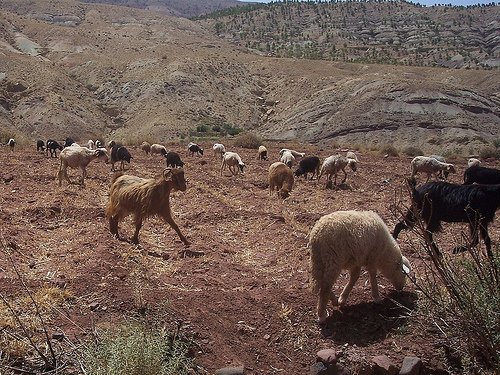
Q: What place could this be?
A: It is a field.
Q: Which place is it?
A: It is a field.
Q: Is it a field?
A: Yes, it is a field.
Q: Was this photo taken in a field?
A: Yes, it was taken in a field.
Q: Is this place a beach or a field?
A: It is a field.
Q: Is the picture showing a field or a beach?
A: It is showing a field.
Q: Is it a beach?
A: No, it is a field.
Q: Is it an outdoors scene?
A: Yes, it is outdoors.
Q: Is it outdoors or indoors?
A: It is outdoors.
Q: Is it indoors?
A: No, it is outdoors.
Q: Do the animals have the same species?
A: No, there are both sheep and goats.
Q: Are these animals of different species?
A: Yes, they are sheep and goats.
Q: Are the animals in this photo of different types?
A: Yes, they are sheep and goats.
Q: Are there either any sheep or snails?
A: Yes, there is a sheep.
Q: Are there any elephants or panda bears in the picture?
A: No, there are no panda bears or elephants.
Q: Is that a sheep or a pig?
A: That is a sheep.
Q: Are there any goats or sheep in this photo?
A: Yes, there is a sheep.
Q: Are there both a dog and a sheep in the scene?
A: No, there is a sheep but no dogs.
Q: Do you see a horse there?
A: No, there are no horses.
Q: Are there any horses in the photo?
A: No, there are no horses.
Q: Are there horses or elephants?
A: No, there are no horses or elephants.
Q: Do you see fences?
A: No, there are no fences.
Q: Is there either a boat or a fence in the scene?
A: No, there are no fences or boats.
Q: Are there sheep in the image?
A: Yes, there is a sheep.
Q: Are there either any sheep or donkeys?
A: Yes, there is a sheep.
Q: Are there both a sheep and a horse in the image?
A: No, there is a sheep but no horses.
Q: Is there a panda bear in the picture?
A: No, there are no panda bears.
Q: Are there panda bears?
A: No, there are no panda bears.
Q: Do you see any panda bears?
A: No, there are no panda bears.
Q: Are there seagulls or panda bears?
A: No, there are no panda bears or seagulls.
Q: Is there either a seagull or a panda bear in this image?
A: No, there are no panda bears or seagulls.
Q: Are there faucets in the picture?
A: No, there are no faucets.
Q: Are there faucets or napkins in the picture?
A: No, there are no faucets or napkins.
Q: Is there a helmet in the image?
A: No, there are no helmets.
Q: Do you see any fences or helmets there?
A: No, there are no helmets or fences.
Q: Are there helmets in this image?
A: No, there are no helmets.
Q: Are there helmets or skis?
A: No, there are no helmets or skis.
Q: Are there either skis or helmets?
A: No, there are no helmets or skis.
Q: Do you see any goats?
A: Yes, there are goats.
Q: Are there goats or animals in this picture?
A: Yes, there are goats.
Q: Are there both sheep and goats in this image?
A: Yes, there are both goats and a sheep.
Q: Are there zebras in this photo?
A: No, there are no zebras.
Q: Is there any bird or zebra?
A: No, there are no zebras or birds.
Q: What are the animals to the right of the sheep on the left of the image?
A: The animals are goats.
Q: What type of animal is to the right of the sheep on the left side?
A: The animals are goats.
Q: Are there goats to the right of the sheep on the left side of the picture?
A: Yes, there are goats to the right of the sheep.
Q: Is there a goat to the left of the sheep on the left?
A: No, the goats are to the right of the sheep.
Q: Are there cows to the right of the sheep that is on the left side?
A: No, there are goats to the right of the sheep.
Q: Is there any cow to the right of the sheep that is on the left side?
A: No, there are goats to the right of the sheep.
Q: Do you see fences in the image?
A: No, there are no fences.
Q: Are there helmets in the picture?
A: No, there are no helmets.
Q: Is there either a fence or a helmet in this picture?
A: No, there are no helmets or fences.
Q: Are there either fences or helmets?
A: No, there are no helmets or fences.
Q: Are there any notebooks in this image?
A: No, there are no notebooks.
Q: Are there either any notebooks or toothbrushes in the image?
A: No, there are no notebooks or toothbrushes.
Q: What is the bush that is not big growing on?
A: The shrub is growing on the mountain.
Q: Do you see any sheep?
A: Yes, there is a sheep.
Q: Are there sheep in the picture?
A: Yes, there is a sheep.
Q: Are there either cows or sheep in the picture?
A: Yes, there is a sheep.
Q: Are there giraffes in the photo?
A: No, there are no giraffes.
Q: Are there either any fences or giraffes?
A: No, there are no giraffes or fences.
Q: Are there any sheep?
A: Yes, there is a sheep.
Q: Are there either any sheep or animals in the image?
A: Yes, there is a sheep.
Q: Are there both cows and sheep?
A: No, there is a sheep but no cows.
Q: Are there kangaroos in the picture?
A: No, there are no kangaroos.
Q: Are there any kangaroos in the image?
A: No, there are no kangaroos.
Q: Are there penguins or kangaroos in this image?
A: No, there are no kangaroos or penguins.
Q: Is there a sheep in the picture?
A: Yes, there is a sheep.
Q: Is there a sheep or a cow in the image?
A: Yes, there is a sheep.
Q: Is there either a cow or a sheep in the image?
A: Yes, there is a sheep.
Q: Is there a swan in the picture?
A: No, there are no swans.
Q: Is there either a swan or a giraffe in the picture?
A: No, there are no swans or giraffes.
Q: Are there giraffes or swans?
A: No, there are no swans or giraffes.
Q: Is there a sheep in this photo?
A: Yes, there is a sheep.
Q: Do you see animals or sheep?
A: Yes, there is a sheep.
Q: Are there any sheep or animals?
A: Yes, there is a sheep.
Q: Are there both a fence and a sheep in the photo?
A: No, there is a sheep but no fences.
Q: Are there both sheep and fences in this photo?
A: No, there is a sheep but no fences.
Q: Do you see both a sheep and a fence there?
A: No, there is a sheep but no fences.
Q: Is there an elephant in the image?
A: No, there are no elephants.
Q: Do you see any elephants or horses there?
A: No, there are no elephants or horses.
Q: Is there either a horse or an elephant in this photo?
A: No, there are no elephants or horses.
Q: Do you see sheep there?
A: Yes, there is a sheep.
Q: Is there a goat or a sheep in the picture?
A: Yes, there is a sheep.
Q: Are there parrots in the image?
A: No, there are no parrots.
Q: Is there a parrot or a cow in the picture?
A: No, there are no parrots or cows.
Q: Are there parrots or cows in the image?
A: No, there are no parrots or cows.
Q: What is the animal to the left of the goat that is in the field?
A: The animal is a sheep.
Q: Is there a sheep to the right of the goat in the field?
A: No, the sheep is to the left of the goat.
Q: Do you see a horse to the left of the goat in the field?
A: No, there is a sheep to the left of the goat.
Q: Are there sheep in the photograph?
A: Yes, there is a sheep.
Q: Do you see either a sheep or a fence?
A: Yes, there is a sheep.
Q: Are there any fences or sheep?
A: Yes, there is a sheep.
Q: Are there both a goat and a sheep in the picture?
A: Yes, there are both a sheep and a goat.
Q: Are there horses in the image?
A: No, there are no horses.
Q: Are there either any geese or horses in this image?
A: No, there are no horses or geese.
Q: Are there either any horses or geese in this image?
A: No, there are no horses or geese.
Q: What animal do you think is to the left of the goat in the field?
A: The animal is a sheep.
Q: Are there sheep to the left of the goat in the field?
A: Yes, there is a sheep to the left of the goat.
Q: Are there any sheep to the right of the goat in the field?
A: No, the sheep is to the left of the goat.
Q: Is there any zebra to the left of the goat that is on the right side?
A: No, there is a sheep to the left of the goat.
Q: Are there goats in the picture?
A: Yes, there is a goat.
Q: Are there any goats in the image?
A: Yes, there is a goat.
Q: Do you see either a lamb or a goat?
A: Yes, there is a goat.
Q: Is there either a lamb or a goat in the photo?
A: Yes, there is a goat.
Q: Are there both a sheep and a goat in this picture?
A: Yes, there are both a goat and a sheep.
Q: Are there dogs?
A: No, there are no dogs.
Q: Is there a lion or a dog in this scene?
A: No, there are no dogs or lions.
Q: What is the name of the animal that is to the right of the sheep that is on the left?
A: The animal is a goat.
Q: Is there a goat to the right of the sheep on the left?
A: Yes, there is a goat to the right of the sheep.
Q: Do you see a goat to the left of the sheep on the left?
A: No, the goat is to the right of the sheep.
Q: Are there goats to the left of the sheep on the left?
A: No, the goat is to the right of the sheep.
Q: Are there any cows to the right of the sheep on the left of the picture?
A: No, there is a goat to the right of the sheep.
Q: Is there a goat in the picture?
A: Yes, there is a goat.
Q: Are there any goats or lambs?
A: Yes, there is a goat.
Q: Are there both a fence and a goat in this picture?
A: No, there is a goat but no fences.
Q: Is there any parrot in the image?
A: No, there are no parrots.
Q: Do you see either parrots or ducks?
A: No, there are no parrots or ducks.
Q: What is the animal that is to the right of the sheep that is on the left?
A: The animal is a goat.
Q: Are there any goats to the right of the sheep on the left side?
A: Yes, there is a goat to the right of the sheep.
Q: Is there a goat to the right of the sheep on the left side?
A: Yes, there is a goat to the right of the sheep.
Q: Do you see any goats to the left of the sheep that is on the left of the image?
A: No, the goat is to the right of the sheep.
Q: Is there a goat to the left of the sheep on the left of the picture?
A: No, the goat is to the right of the sheep.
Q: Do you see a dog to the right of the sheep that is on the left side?
A: No, there is a goat to the right of the sheep.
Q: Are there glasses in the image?
A: No, there are no glasses.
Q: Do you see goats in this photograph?
A: Yes, there is a goat.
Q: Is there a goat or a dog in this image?
A: Yes, there is a goat.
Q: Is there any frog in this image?
A: No, there are no frogs.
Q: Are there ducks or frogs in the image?
A: No, there are no frogs or ducks.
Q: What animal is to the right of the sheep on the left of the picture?
A: The animal is a goat.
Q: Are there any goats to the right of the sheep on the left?
A: Yes, there is a goat to the right of the sheep.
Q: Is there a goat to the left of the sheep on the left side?
A: No, the goat is to the right of the sheep.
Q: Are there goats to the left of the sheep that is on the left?
A: No, the goat is to the right of the sheep.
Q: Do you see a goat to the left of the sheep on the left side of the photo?
A: No, the goat is to the right of the sheep.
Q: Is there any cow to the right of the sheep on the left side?
A: No, there is a goat to the right of the sheep.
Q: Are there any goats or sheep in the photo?
A: Yes, there is a goat.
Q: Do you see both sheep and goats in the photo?
A: Yes, there are both a goat and a sheep.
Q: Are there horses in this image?
A: No, there are no horses.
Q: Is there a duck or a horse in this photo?
A: No, there are no horses or ducks.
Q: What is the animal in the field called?
A: The animal is a goat.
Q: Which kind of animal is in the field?
A: The animal is a goat.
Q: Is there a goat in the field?
A: Yes, there is a goat in the field.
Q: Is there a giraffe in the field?
A: No, there is a goat in the field.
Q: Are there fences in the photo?
A: No, there are no fences.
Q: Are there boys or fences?
A: No, there are no fences or boys.